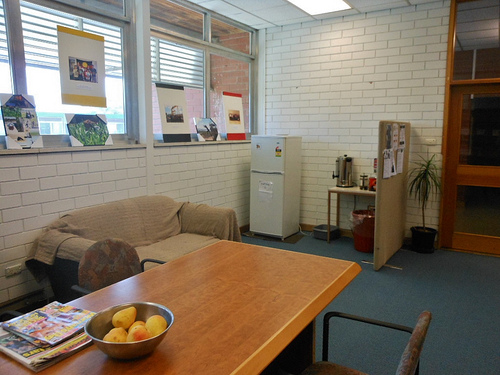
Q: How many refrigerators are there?
A: One.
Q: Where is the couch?
A: Under the window.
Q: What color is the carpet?
A: Blue.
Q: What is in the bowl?
A: Fruit.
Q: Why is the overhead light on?
A: For extra light.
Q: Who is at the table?
A: No one.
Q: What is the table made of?
A: Wood.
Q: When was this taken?
A: During the day.